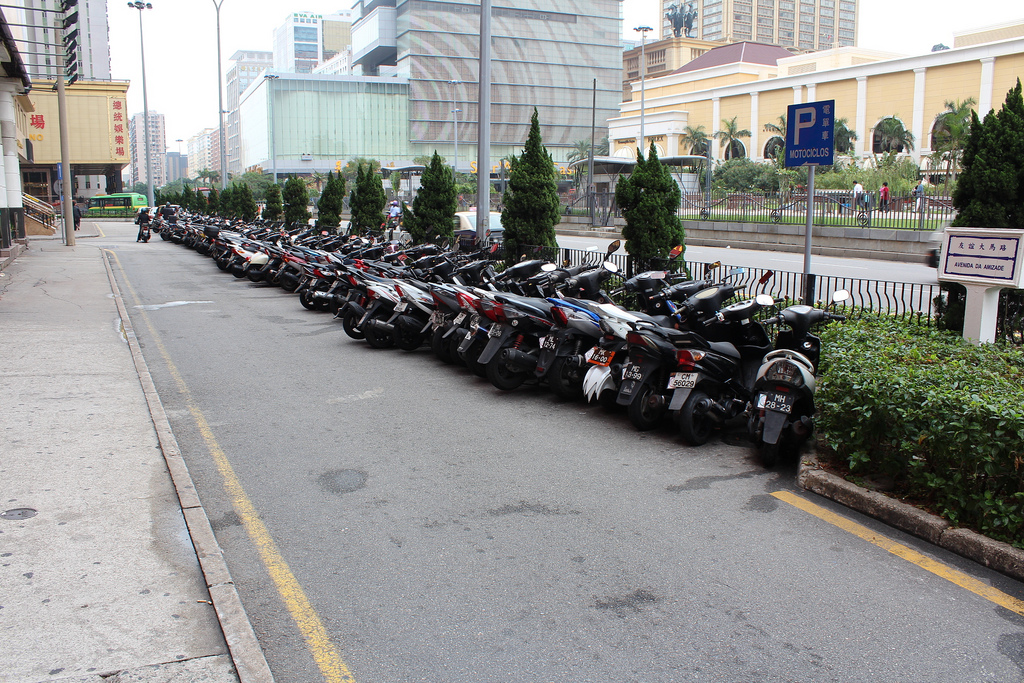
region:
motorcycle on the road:
[753, 297, 818, 494]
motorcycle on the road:
[655, 291, 713, 440]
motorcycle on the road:
[162, 209, 195, 248]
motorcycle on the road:
[200, 214, 240, 273]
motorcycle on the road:
[269, 227, 331, 320]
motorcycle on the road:
[428, 244, 482, 340]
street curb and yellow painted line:
[133, 363, 330, 680]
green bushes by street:
[799, 285, 1021, 514]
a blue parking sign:
[764, 82, 857, 272]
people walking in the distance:
[843, 159, 920, 221]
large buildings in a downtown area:
[234, 9, 735, 169]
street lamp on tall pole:
[122, 1, 168, 229]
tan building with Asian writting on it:
[15, 57, 155, 178]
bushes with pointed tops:
[498, 101, 699, 273]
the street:
[369, 542, 541, 648]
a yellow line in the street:
[285, 626, 356, 680]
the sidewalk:
[92, 579, 185, 647]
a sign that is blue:
[783, 105, 844, 163]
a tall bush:
[622, 159, 692, 262]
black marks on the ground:
[17, 560, 44, 586]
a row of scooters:
[124, 183, 872, 474]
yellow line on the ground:
[84, 227, 385, 676]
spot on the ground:
[299, 430, 413, 558]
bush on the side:
[775, 262, 1020, 595]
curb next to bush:
[791, 435, 1022, 616]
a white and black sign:
[927, 215, 1019, 329]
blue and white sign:
[759, 88, 842, 180]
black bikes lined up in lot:
[589, 234, 698, 431]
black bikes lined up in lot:
[494, 244, 572, 358]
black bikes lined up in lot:
[336, 236, 441, 345]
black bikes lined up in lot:
[169, 221, 242, 279]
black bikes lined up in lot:
[236, 200, 284, 278]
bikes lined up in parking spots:
[181, 210, 220, 248]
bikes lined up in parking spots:
[239, 204, 316, 328]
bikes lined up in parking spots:
[356, 232, 465, 362]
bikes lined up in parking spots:
[751, 262, 832, 440]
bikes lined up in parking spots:
[476, 200, 610, 398]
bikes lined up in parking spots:
[641, 265, 784, 444]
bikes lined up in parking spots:
[450, 205, 590, 405]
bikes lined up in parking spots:
[282, 186, 369, 370]